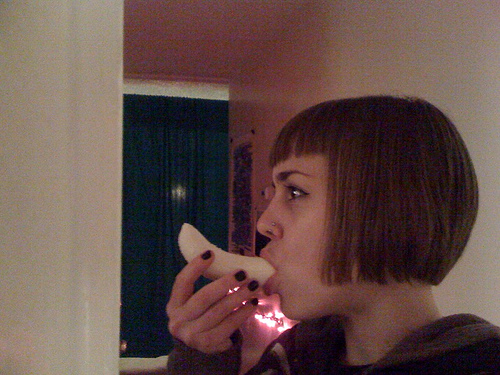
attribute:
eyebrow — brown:
[274, 167, 311, 183]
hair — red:
[240, 86, 488, 331]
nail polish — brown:
[188, 248, 264, 302]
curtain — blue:
[124, 94, 234, 357]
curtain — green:
[111, 106, 253, 286]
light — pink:
[226, 282, 292, 332]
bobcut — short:
[268, 92, 478, 287]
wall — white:
[1, 3, 118, 370]